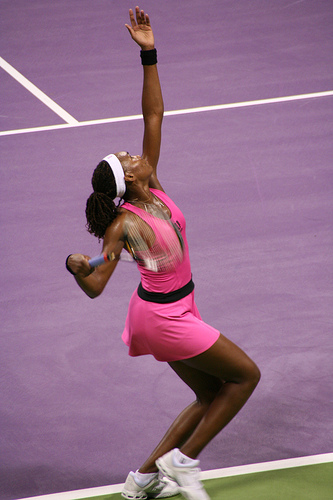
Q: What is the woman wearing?
A: A dress.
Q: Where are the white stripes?
A: On the tennis court.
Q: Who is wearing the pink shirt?
A: The woman.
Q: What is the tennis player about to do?
A: Hit the ball.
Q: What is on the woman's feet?
A: White tennis shoes.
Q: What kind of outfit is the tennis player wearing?
A: Pink skirt.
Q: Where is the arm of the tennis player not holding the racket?
A: Straight up in the air.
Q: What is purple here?
A: The ground.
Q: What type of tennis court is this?
A: Purple and white.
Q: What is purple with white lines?
A: The tennis court.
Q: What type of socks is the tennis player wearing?
A: Short white socks.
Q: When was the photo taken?
A: Daytime.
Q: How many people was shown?
A: One.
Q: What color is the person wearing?
A: Pink.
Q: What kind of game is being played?
A: Tennis.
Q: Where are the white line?
A: Tennis court.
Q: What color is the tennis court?
A: Purple.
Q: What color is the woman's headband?
A: White.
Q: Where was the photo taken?
A: Stands at a female tennis match.